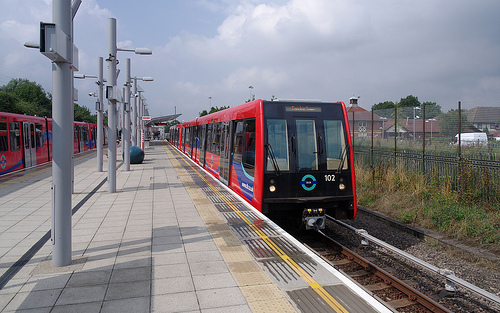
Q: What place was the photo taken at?
A: It was taken at the train station.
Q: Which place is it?
A: It is a train station.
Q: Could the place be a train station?
A: Yes, it is a train station.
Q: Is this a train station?
A: Yes, it is a train station.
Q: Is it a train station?
A: Yes, it is a train station.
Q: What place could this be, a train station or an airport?
A: It is a train station.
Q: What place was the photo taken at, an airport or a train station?
A: It was taken at a train station.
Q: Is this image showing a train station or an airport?
A: It is showing a train station.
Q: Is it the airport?
A: No, it is the train station.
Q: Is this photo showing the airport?
A: No, the picture is showing the train station.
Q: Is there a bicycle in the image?
A: No, there are no bicycles.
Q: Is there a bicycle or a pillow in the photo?
A: No, there are no bicycles or pillows.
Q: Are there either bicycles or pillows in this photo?
A: No, there are no bicycles or pillows.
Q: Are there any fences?
A: Yes, there is a fence.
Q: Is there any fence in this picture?
A: Yes, there is a fence.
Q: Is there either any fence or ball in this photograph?
A: Yes, there is a fence.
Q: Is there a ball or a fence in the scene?
A: Yes, there is a fence.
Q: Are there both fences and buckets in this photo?
A: No, there is a fence but no buckets.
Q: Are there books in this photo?
A: No, there are no books.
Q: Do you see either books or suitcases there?
A: No, there are no books or suitcases.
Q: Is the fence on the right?
A: Yes, the fence is on the right of the image.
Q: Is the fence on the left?
A: No, the fence is on the right of the image.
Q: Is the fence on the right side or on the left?
A: The fence is on the right of the image.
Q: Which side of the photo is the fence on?
A: The fence is on the right of the image.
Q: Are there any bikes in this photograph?
A: No, there are no bikes.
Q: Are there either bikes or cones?
A: No, there are no bikes or cones.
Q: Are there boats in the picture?
A: No, there are no boats.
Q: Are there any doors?
A: Yes, there is a door.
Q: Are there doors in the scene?
A: Yes, there is a door.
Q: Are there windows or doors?
A: Yes, there is a door.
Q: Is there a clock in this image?
A: No, there are no clocks.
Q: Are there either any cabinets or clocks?
A: No, there are no clocks or cabinets.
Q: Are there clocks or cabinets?
A: No, there are no clocks or cabinets.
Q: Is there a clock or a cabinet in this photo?
A: No, there are no clocks or cabinets.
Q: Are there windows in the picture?
A: Yes, there is a window.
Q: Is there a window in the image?
A: Yes, there is a window.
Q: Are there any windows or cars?
A: Yes, there is a window.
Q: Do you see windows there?
A: Yes, there is a window.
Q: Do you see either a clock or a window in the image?
A: Yes, there is a window.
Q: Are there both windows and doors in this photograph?
A: Yes, there are both a window and doors.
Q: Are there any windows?
A: Yes, there is a window.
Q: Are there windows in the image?
A: Yes, there is a window.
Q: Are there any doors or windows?
A: Yes, there is a window.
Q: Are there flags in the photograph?
A: No, there are no flags.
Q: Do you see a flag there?
A: No, there are no flags.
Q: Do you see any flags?
A: No, there are no flags.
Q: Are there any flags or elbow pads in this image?
A: No, there are no flags or elbow pads.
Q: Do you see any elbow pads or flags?
A: No, there are no flags or elbow pads.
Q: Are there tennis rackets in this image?
A: No, there are no tennis rackets.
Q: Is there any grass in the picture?
A: Yes, there is grass.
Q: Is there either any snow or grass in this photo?
A: Yes, there is grass.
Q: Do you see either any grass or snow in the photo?
A: Yes, there is grass.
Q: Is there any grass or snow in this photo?
A: Yes, there is grass.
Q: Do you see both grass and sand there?
A: No, there is grass but no sand.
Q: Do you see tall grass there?
A: Yes, there is tall grass.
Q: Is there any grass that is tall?
A: Yes, there is grass that is tall.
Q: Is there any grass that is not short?
A: Yes, there is tall grass.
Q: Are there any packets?
A: No, there are no packets.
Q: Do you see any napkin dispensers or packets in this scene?
A: No, there are no packets or napkin dispensers.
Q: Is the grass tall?
A: Yes, the grass is tall.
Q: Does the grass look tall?
A: Yes, the grass is tall.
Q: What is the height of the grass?
A: The grass is tall.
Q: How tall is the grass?
A: The grass is tall.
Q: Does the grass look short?
A: No, the grass is tall.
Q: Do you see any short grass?
A: No, there is grass but it is tall.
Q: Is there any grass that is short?
A: No, there is grass but it is tall.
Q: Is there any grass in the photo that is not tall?
A: No, there is grass but it is tall.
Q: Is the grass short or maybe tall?
A: The grass is tall.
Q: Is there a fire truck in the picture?
A: No, there are no fire trucks.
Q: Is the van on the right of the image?
A: Yes, the van is on the right of the image.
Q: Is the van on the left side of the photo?
A: No, the van is on the right of the image.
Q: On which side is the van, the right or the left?
A: The van is on the right of the image.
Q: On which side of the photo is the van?
A: The van is on the right of the image.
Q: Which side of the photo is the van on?
A: The van is on the right of the image.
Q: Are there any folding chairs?
A: No, there are no folding chairs.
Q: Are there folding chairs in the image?
A: No, there are no folding chairs.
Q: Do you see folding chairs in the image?
A: No, there are no folding chairs.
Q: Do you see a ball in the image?
A: Yes, there is a ball.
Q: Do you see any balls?
A: Yes, there is a ball.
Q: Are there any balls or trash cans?
A: Yes, there is a ball.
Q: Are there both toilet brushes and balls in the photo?
A: No, there is a ball but no toilet brushes.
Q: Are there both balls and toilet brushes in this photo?
A: No, there is a ball but no toilet brushes.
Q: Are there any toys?
A: No, there are no toys.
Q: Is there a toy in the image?
A: No, there are no toys.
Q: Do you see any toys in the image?
A: No, there are no toys.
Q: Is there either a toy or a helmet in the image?
A: No, there are no toys or helmets.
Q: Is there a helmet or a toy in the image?
A: No, there are no toys or helmets.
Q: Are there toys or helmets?
A: No, there are no toys or helmets.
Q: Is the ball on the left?
A: Yes, the ball is on the left of the image.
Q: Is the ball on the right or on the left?
A: The ball is on the left of the image.